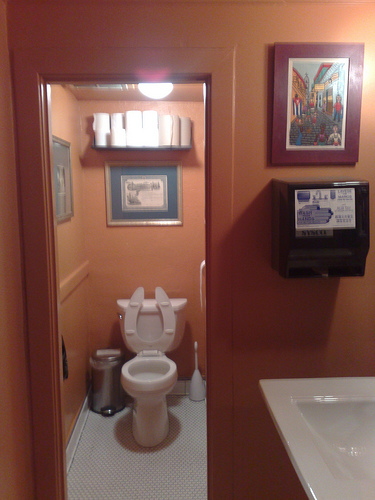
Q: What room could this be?
A: It is a bathroom.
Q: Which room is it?
A: It is a bathroom.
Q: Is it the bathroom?
A: Yes, it is the bathroom.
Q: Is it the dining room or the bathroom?
A: It is the bathroom.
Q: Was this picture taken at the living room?
A: No, the picture was taken in the bathroom.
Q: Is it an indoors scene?
A: Yes, it is indoors.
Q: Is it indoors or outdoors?
A: It is indoors.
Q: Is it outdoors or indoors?
A: It is indoors.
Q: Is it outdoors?
A: No, it is indoors.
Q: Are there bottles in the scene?
A: No, there are no bottles.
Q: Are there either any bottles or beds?
A: No, there are no bottles or beds.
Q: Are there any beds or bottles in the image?
A: No, there are no bottles or beds.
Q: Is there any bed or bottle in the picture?
A: No, there are no bottles or beds.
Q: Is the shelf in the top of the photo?
A: Yes, the shelf is in the top of the image.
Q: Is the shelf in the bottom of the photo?
A: No, the shelf is in the top of the image.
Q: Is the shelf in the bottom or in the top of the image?
A: The shelf is in the top of the image.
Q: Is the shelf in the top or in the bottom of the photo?
A: The shelf is in the top of the image.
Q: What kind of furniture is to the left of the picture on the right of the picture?
A: The piece of furniture is a shelf.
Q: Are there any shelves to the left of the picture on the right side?
A: Yes, there is a shelf to the left of the picture.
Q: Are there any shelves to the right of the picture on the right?
A: No, the shelf is to the left of the picture.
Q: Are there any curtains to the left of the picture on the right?
A: No, there is a shelf to the left of the picture.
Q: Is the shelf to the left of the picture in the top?
A: Yes, the shelf is to the left of the picture.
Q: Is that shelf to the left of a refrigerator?
A: No, the shelf is to the left of the picture.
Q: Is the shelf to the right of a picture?
A: No, the shelf is to the left of a picture.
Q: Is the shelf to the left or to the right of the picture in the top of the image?
A: The shelf is to the left of the picture.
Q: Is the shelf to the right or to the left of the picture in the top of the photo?
A: The shelf is to the left of the picture.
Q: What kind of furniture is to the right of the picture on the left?
A: The piece of furniture is a shelf.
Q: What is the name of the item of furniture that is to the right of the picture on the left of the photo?
A: The piece of furniture is a shelf.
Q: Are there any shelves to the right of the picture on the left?
A: Yes, there is a shelf to the right of the picture.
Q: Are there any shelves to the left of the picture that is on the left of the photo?
A: No, the shelf is to the right of the picture.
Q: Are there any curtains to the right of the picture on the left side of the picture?
A: No, there is a shelf to the right of the picture.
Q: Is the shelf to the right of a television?
A: No, the shelf is to the right of a picture.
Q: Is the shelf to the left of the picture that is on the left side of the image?
A: No, the shelf is to the right of the picture.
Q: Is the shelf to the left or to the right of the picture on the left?
A: The shelf is to the right of the picture.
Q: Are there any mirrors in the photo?
A: No, there are no mirrors.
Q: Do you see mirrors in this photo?
A: No, there are no mirrors.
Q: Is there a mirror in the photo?
A: No, there are no mirrors.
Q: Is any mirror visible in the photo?
A: No, there are no mirrors.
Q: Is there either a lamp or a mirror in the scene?
A: No, there are no mirrors or lamps.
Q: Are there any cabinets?
A: No, there are no cabinets.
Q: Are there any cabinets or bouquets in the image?
A: No, there are no cabinets or bouquets.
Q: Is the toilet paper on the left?
A: Yes, the toilet paper is on the left of the image.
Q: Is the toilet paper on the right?
A: No, the toilet paper is on the left of the image.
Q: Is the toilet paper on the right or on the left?
A: The toilet paper is on the left of the image.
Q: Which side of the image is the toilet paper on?
A: The toilet paper is on the left of the image.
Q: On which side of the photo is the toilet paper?
A: The toilet paper is on the left of the image.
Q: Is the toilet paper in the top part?
A: Yes, the toilet paper is in the top of the image.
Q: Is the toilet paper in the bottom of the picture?
A: No, the toilet paper is in the top of the image.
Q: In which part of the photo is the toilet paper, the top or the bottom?
A: The toilet paper is in the top of the image.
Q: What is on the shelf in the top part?
A: The toilet paper is on the shelf.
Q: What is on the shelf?
A: The toilet paper is on the shelf.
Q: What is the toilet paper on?
A: The toilet paper is on the shelf.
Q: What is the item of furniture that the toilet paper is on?
A: The piece of furniture is a shelf.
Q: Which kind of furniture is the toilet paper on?
A: The toilet paper is on the shelf.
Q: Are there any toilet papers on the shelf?
A: Yes, there is a toilet paper on the shelf.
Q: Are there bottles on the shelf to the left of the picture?
A: No, there is a toilet paper on the shelf.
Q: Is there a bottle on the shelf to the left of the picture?
A: No, there is a toilet paper on the shelf.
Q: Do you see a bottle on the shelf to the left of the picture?
A: No, there is a toilet paper on the shelf.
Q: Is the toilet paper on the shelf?
A: Yes, the toilet paper is on the shelf.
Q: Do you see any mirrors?
A: No, there are no mirrors.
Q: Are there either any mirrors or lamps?
A: No, there are no mirrors or lamps.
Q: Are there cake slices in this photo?
A: No, there are no cake slices.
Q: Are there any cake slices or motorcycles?
A: No, there are no cake slices or motorcycles.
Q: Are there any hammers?
A: No, there are no hammers.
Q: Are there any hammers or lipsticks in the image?
A: No, there are no hammers or lipsticks.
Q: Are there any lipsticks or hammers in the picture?
A: No, there are no hammers or lipsticks.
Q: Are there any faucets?
A: No, there are no faucets.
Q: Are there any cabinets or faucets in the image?
A: No, there are no faucets or cabinets.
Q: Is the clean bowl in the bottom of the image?
A: Yes, the bowl is in the bottom of the image.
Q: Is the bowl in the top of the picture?
A: No, the bowl is in the bottom of the image.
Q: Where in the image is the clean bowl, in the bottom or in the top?
A: The bowl is in the bottom of the image.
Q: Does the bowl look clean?
A: Yes, the bowl is clean.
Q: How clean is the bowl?
A: The bowl is clean.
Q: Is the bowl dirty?
A: No, the bowl is clean.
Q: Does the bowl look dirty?
A: No, the bowl is clean.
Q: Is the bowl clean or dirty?
A: The bowl is clean.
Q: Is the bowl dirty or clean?
A: The bowl is clean.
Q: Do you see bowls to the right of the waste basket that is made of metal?
A: Yes, there is a bowl to the right of the waste basket.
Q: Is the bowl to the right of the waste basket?
A: Yes, the bowl is to the right of the waste basket.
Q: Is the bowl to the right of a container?
A: No, the bowl is to the right of the waste basket.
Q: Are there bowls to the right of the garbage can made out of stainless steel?
A: Yes, there is a bowl to the right of the trash can.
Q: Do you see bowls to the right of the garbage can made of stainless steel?
A: Yes, there is a bowl to the right of the trash can.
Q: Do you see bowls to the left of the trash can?
A: No, the bowl is to the right of the trash can.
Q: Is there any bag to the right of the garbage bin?
A: No, there is a bowl to the right of the garbage bin.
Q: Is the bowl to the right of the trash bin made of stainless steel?
A: Yes, the bowl is to the right of the garbage can.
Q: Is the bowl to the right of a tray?
A: No, the bowl is to the right of the garbage can.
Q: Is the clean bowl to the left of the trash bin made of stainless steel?
A: No, the bowl is to the right of the trash bin.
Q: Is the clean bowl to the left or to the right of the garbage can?
A: The bowl is to the right of the garbage can.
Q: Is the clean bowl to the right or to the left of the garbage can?
A: The bowl is to the right of the garbage can.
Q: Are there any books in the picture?
A: No, there are no books.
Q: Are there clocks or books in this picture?
A: No, there are no books or clocks.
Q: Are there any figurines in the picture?
A: No, there are no figurines.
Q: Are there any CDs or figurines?
A: No, there are no figurines or cds.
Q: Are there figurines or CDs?
A: No, there are no figurines or cds.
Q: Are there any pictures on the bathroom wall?
A: Yes, there is a picture on the wall.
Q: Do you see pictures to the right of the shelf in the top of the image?
A: Yes, there is a picture to the right of the shelf.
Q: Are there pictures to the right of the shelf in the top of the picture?
A: Yes, there is a picture to the right of the shelf.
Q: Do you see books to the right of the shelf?
A: No, there is a picture to the right of the shelf.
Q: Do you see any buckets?
A: No, there are no buckets.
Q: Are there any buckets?
A: No, there are no buckets.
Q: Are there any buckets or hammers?
A: No, there are no buckets or hammers.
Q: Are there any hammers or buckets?
A: No, there are no buckets or hammers.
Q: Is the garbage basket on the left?
A: Yes, the garbage basket is on the left of the image.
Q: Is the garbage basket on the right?
A: No, the garbage basket is on the left of the image.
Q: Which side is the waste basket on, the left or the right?
A: The waste basket is on the left of the image.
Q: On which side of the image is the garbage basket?
A: The garbage basket is on the left of the image.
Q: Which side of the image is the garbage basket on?
A: The garbage basket is on the left of the image.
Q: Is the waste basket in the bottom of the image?
A: Yes, the waste basket is in the bottom of the image.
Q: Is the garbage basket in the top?
A: No, the garbage basket is in the bottom of the image.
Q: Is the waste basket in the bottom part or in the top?
A: The waste basket is in the bottom of the image.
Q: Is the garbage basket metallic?
A: Yes, the garbage basket is metallic.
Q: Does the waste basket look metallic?
A: Yes, the waste basket is metallic.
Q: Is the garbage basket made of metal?
A: Yes, the garbage basket is made of metal.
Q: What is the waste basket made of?
A: The waste basket is made of metal.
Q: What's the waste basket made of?
A: The waste basket is made of metal.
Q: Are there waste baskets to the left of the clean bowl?
A: Yes, there is a waste basket to the left of the bowl.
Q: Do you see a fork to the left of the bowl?
A: No, there is a waste basket to the left of the bowl.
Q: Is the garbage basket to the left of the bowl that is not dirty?
A: Yes, the garbage basket is to the left of the bowl.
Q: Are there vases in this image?
A: No, there are no vases.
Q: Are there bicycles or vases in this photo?
A: No, there are no vases or bicycles.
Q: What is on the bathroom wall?
A: The picture is on the wall.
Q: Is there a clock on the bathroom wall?
A: No, there is a picture on the wall.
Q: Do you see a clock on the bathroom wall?
A: No, there is a picture on the wall.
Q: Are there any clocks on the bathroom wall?
A: No, there is a picture on the wall.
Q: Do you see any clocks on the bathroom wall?
A: No, there is a picture on the wall.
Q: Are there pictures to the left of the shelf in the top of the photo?
A: Yes, there is a picture to the left of the shelf.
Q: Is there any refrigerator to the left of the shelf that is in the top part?
A: No, there is a picture to the left of the shelf.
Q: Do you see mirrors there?
A: No, there are no mirrors.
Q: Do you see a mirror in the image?
A: No, there are no mirrors.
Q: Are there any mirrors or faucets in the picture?
A: No, there are no mirrors or faucets.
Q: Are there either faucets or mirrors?
A: No, there are no mirrors or faucets.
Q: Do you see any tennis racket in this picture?
A: No, there are no rackets.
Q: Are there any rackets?
A: No, there are no rackets.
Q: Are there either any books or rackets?
A: No, there are no rackets or books.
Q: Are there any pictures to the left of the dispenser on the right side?
A: Yes, there is a picture to the left of the dispenser.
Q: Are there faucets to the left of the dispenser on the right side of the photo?
A: No, there is a picture to the left of the dispenser.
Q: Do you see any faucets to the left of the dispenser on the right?
A: No, there is a picture to the left of the dispenser.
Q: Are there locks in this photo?
A: No, there are no locks.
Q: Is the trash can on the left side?
A: Yes, the trash can is on the left of the image.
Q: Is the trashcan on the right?
A: No, the trashcan is on the left of the image.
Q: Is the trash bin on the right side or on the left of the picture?
A: The trash bin is on the left of the image.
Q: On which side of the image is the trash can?
A: The trash can is on the left of the image.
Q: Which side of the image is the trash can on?
A: The trash can is on the left of the image.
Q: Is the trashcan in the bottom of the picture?
A: Yes, the trashcan is in the bottom of the image.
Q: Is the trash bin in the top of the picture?
A: No, the trash bin is in the bottom of the image.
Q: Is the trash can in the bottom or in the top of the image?
A: The trash can is in the bottom of the image.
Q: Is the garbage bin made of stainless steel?
A: Yes, the garbage bin is made of stainless steel.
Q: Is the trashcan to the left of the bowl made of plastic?
A: No, the trash bin is made of stainless steel.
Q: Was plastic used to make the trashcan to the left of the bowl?
A: No, the trash bin is made of stainless steel.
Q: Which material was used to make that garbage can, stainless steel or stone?
A: The garbage can is made of stainless steel.